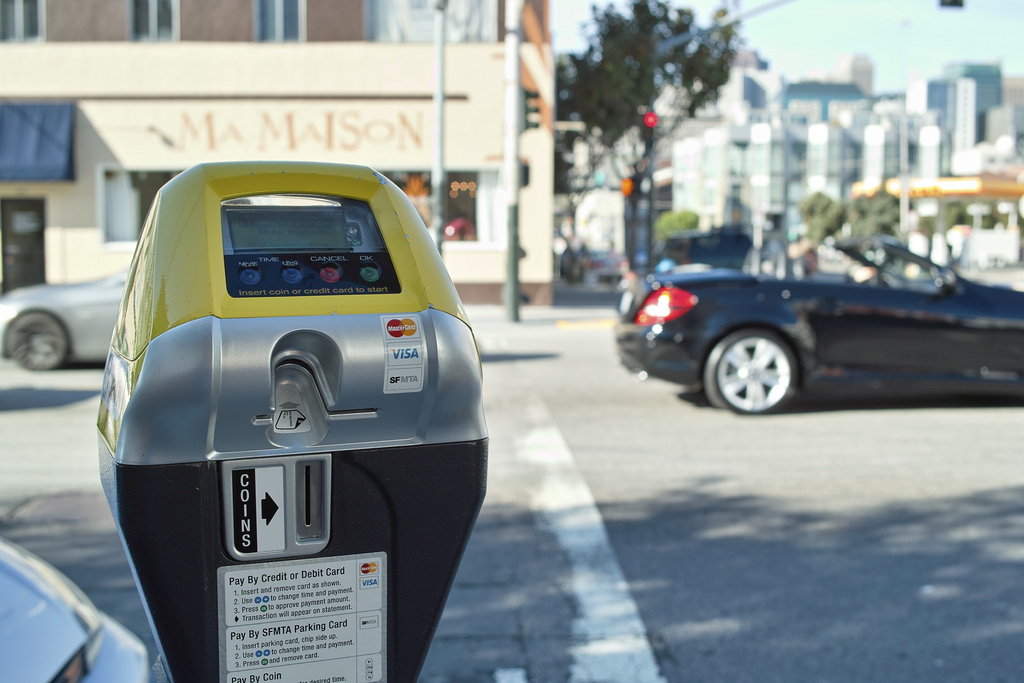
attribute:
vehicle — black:
[610, 229, 1022, 414]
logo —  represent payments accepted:
[382, 367, 428, 391]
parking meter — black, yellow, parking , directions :
[96, 155, 512, 678]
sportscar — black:
[616, 229, 1022, 422]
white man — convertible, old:
[784, 225, 826, 276]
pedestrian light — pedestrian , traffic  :
[616, 169, 645, 205]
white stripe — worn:
[499, 376, 664, 680]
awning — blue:
[0, 99, 86, 189]